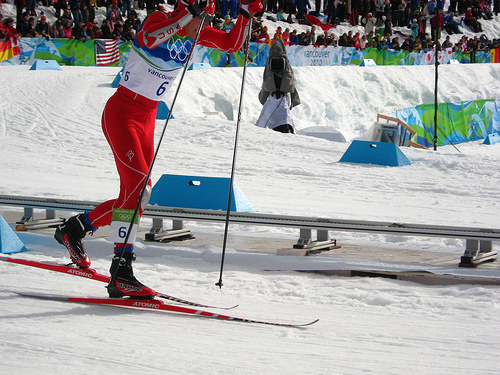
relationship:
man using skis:
[43, 8, 270, 265] [0, 249, 310, 341]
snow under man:
[7, 67, 500, 374] [43, 8, 270, 265]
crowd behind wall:
[4, 0, 499, 51] [7, 38, 497, 79]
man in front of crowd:
[43, 8, 270, 265] [4, 0, 499, 51]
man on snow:
[43, 8, 270, 265] [7, 67, 500, 374]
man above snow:
[43, 8, 270, 265] [7, 67, 500, 374]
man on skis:
[50, 0, 265, 301] [0, 243, 317, 330]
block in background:
[340, 138, 407, 169] [271, 1, 482, 173]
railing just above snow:
[235, 38, 482, 68] [333, 68, 408, 104]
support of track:
[294, 231, 317, 251] [1, 197, 484, 268]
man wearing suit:
[50, 0, 265, 301] [92, 8, 255, 247]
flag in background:
[87, 36, 123, 69] [0, 0, 484, 67]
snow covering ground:
[318, 73, 390, 113] [1, 117, 483, 365]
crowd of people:
[0, 0, 499, 51] [54, 4, 121, 33]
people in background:
[54, 4, 121, 33] [2, 1, 484, 81]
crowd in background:
[0, 0, 499, 51] [2, 1, 484, 81]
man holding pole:
[50, 0, 265, 301] [216, 19, 252, 290]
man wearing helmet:
[50, 0, 265, 301] [173, 0, 215, 16]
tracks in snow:
[20, 81, 89, 161] [7, 67, 500, 374]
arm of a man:
[139, 3, 202, 48] [43, 8, 270, 265]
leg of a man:
[98, 96, 152, 206] [43, 8, 270, 265]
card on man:
[140, 68, 176, 106] [43, 8, 270, 265]